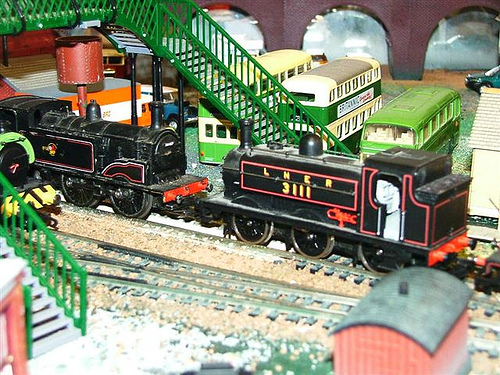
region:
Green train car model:
[355, 83, 464, 162]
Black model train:
[2, 95, 498, 290]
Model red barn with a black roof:
[326, 265, 473, 372]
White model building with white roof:
[465, 85, 499, 245]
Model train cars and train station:
[0, 2, 498, 371]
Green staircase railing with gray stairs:
[1, 173, 88, 363]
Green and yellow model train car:
[195, 47, 315, 167]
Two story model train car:
[277, 53, 384, 155]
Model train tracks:
[24, 223, 499, 354]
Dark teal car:
[464, 60, 499, 88]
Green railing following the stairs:
[3, 2, 368, 362]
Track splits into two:
[10, 218, 334, 321]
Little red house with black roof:
[324, 264, 476, 374]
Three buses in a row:
[188, 44, 465, 164]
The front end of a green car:
[463, 64, 498, 96]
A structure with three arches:
[173, 0, 499, 81]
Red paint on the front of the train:
[158, 177, 208, 207]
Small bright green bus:
[354, 80, 464, 165]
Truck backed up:
[18, 76, 192, 140]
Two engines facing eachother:
[0, 87, 479, 289]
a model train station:
[0, 4, 495, 365]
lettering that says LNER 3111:
[251, 163, 346, 210]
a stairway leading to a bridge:
[123, 13, 370, 192]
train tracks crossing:
[125, 240, 251, 320]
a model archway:
[412, 9, 479, 82]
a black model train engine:
[14, 82, 205, 229]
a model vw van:
[395, 62, 468, 159]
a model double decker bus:
[186, 79, 267, 182]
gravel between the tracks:
[120, 228, 183, 262]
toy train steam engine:
[195, 106, 477, 276]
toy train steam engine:
[0, 88, 212, 205]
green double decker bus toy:
[272, 33, 386, 157]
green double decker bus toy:
[187, 39, 312, 174]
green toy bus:
[347, 76, 467, 173]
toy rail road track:
[7, 202, 498, 360]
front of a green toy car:
[455, 53, 497, 90]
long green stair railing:
[110, 0, 357, 175]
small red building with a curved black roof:
[294, 262, 474, 370]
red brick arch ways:
[141, 1, 495, 86]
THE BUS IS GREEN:
[345, 78, 460, 185]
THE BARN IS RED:
[316, 265, 487, 371]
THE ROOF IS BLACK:
[326, 256, 472, 361]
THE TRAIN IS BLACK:
[206, 105, 484, 290]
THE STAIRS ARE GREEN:
[118, 3, 374, 213]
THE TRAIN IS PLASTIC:
[15, 95, 478, 295]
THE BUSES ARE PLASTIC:
[180, 27, 480, 213]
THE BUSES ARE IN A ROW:
[190, 31, 465, 196]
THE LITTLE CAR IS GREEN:
[461, 56, 497, 96]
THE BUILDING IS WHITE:
[457, 79, 499, 264]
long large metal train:
[0, 83, 478, 278]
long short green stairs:
[0, 175, 87, 362]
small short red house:
[327, 270, 476, 373]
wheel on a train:
[346, 240, 386, 270]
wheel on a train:
[284, 215, 342, 260]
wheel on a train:
[228, 190, 269, 241]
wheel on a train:
[100, 176, 154, 218]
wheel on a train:
[57, 167, 111, 217]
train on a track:
[350, 148, 477, 268]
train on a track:
[116, 110, 206, 212]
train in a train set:
[265, 35, 311, 67]